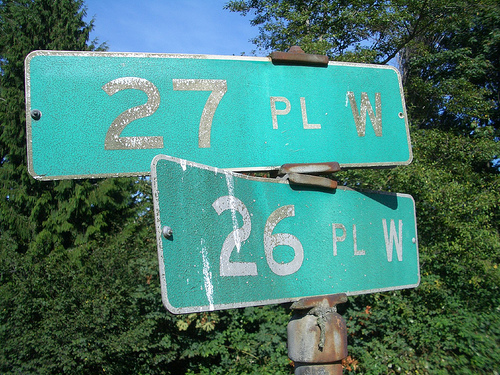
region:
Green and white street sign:
[25, 49, 409, 169]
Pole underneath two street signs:
[284, 298, 350, 373]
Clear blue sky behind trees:
[82, 1, 276, 58]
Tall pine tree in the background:
[2, 0, 152, 258]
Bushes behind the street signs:
[4, 216, 499, 373]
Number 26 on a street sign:
[212, 194, 306, 281]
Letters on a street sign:
[326, 210, 408, 273]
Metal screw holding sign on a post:
[158, 222, 172, 238]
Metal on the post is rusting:
[278, 161, 344, 175]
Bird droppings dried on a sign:
[174, 154, 246, 311]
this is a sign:
[24, 37, 445, 184]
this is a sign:
[144, 158, 430, 318]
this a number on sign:
[77, 71, 169, 165]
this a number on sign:
[164, 63, 236, 154]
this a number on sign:
[199, 190, 267, 283]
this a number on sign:
[256, 195, 311, 275]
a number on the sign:
[204, 193, 257, 308]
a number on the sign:
[347, 215, 367, 257]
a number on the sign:
[375, 206, 405, 261]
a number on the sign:
[328, 77, 389, 148]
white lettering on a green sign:
[218, 191, 403, 272]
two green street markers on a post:
[31, 35, 423, 305]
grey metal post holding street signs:
[242, 51, 394, 370]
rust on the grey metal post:
[292, 301, 356, 371]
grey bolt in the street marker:
[161, 220, 183, 242]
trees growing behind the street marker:
[44, 198, 158, 362]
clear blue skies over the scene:
[115, 0, 203, 47]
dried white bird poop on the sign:
[192, 249, 223, 309]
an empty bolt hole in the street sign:
[394, 105, 408, 122]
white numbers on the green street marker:
[201, 188, 299, 286]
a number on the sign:
[90, 60, 169, 155]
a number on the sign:
[172, 68, 227, 152]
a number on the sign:
[257, 197, 302, 307]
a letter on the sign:
[256, 75, 292, 139]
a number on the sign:
[294, 83, 323, 138]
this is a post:
[163, 53, 360, 195]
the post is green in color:
[239, 67, 274, 109]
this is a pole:
[283, 301, 350, 368]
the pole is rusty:
[295, 298, 346, 371]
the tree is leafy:
[435, 200, 495, 314]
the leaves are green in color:
[433, 28, 486, 128]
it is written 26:
[200, 189, 320, 279]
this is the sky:
[138, 3, 205, 44]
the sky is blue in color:
[128, 3, 198, 43]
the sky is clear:
[125, 4, 210, 44]